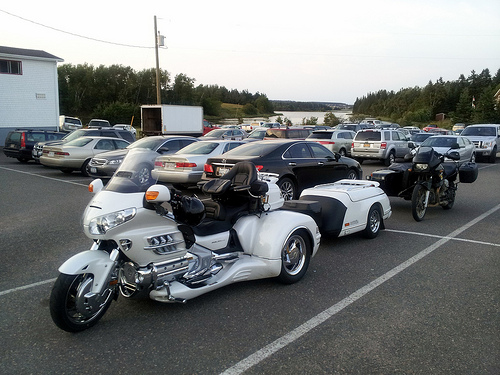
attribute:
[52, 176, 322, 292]
motorcycle — white, pulling, black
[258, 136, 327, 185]
car — black, colored, parked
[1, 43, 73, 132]
building — white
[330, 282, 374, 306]
strip — white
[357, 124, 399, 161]
suv — tan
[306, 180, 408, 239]
trailer — white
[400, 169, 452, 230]
bike — dirt bike, black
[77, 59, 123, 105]
tree — green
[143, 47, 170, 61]
telephone pole — brown, electrical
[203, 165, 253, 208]
seat — leather